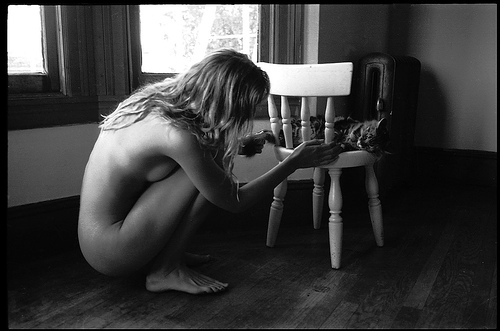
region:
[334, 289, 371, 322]
Brown wood floor grain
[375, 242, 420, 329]
Brown wood floor grain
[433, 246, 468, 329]
Brown wood floor grain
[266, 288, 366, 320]
Brown wood floor grain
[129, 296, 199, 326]
Brown wood floor grain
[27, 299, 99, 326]
Brown wood floor grain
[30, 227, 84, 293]
Brown wood floor grain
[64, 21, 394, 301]
Naked lady on the floor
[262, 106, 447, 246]
Cat in a white chair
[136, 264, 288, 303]
Bare foot on the floor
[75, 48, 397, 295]
Naked woman touching chair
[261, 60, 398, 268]
Cat laying on chair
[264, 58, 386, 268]
Wooden chair sitting on floor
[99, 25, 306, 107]
Open window in background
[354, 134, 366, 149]
White fur on cat's face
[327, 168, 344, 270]
Spindled leg on chair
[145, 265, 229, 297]
Woman's bare foot on floor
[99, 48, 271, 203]
Blonde hair on woman's head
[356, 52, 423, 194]
Storage container in background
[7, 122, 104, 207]
White wall in background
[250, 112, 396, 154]
cat sleeping on chair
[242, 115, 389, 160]
cat laying down on small white chair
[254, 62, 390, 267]
small wooden white chair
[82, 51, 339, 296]
woman bending down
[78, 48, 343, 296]
woman with blond hair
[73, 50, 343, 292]
woman holding cat's tail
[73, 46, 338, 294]
naked woman next to chair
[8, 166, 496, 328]
wooden floor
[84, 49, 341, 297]
woman interacting with cat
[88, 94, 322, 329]
The woman is naked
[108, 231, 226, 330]
These are feet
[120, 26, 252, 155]
The hair is long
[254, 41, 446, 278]
This is a chair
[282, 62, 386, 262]
The chair is made of wood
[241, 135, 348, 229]
These are hands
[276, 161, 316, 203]
This is a wrist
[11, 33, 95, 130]
This is a window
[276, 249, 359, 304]
This is a wooden floor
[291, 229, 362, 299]
The chair is white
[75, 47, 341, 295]
Naked woman crouching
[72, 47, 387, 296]
Naked woman next to a small chair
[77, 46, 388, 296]
Naked woman touching a small chair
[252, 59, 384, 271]
Small white wood chair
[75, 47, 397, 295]
Naked woman petting her cat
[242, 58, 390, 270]
Cat lying on a white chair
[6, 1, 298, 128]
Windows in a thick wood frame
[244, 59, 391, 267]
Cat sleeping on a wood chair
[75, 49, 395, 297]
Naked woman playing with a cats tail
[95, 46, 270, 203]
Long blonde messy hair